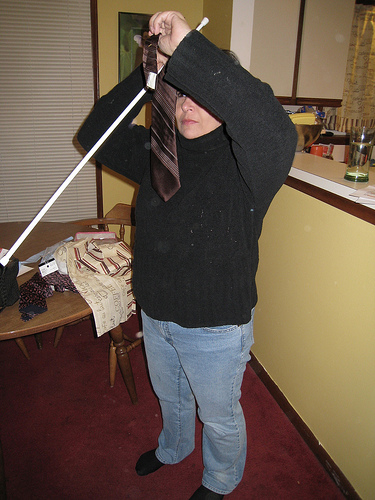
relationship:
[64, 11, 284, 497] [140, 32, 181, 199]
woman holding tie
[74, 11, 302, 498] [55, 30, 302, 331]
woman wearing sweater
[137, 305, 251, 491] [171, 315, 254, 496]
jeans covering legs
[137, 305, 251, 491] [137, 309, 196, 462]
jeans covering legs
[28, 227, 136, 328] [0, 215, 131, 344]
mess on table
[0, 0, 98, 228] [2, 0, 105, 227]
blinds covering door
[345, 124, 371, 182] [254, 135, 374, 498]
glass on counter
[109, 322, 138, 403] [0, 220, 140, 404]
leg on table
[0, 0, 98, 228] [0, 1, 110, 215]
blinds are on window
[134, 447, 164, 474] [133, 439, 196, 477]
sock covering a foot